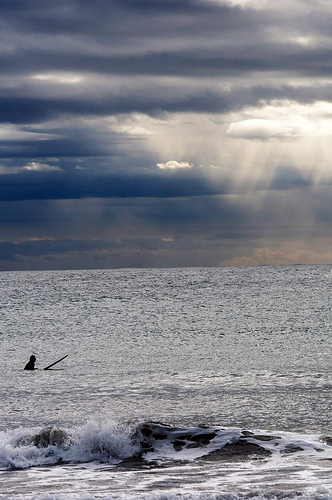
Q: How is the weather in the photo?
A: It is cloudy.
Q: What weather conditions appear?
A: It is cloudy.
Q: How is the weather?
A: It is cloudy.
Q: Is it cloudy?
A: Yes, it is cloudy.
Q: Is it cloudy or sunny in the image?
A: It is cloudy.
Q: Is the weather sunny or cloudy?
A: It is cloudy.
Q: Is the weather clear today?
A: No, it is cloudy.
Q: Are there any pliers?
A: No, there are no pliers.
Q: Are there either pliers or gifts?
A: No, there are no pliers or gifts.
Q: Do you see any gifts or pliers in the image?
A: No, there are no pliers or gifts.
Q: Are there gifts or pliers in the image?
A: No, there are no pliers or gifts.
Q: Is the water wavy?
A: Yes, the water is wavy.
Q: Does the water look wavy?
A: Yes, the water is wavy.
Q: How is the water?
A: The water is wavy.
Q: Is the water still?
A: No, the water is wavy.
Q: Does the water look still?
A: No, the water is wavy.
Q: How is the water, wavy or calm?
A: The water is wavy.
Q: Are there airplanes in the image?
A: No, there are no airplanes.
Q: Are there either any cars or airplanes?
A: No, there are no airplanes or cars.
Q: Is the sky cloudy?
A: Yes, the sky is cloudy.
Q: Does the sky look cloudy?
A: Yes, the sky is cloudy.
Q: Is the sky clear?
A: No, the sky is cloudy.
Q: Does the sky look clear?
A: No, the sky is cloudy.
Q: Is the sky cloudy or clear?
A: The sky is cloudy.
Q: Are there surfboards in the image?
A: Yes, there is a surfboard.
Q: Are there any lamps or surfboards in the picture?
A: Yes, there is a surfboard.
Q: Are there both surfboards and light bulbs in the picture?
A: No, there is a surfboard but no light bulbs.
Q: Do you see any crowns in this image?
A: No, there are no crowns.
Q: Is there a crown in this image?
A: No, there are no crowns.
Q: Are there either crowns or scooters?
A: No, there are no crowns or scooters.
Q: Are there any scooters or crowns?
A: No, there are no crowns or scooters.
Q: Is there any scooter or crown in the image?
A: No, there are no crowns or scooters.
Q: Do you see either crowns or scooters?
A: No, there are no crowns or scooters.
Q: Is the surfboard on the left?
A: Yes, the surfboard is on the left of the image.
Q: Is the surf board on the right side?
A: No, the surf board is on the left of the image.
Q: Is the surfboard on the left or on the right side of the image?
A: The surfboard is on the left of the image.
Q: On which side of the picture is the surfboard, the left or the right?
A: The surfboard is on the left of the image.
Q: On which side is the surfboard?
A: The surfboard is on the left of the image.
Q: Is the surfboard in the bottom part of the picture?
A: Yes, the surfboard is in the bottom of the image.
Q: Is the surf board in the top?
A: No, the surf board is in the bottom of the image.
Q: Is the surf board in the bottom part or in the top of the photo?
A: The surf board is in the bottom of the image.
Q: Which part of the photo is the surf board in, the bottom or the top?
A: The surf board is in the bottom of the image.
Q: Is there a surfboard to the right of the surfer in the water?
A: Yes, there is a surfboard to the right of the surfer.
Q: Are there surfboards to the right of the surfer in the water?
A: Yes, there is a surfboard to the right of the surfer.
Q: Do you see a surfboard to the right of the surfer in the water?
A: Yes, there is a surfboard to the right of the surfer.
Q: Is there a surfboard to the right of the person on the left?
A: Yes, there is a surfboard to the right of the surfer.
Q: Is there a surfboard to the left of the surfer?
A: No, the surfboard is to the right of the surfer.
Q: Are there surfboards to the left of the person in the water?
A: No, the surfboard is to the right of the surfer.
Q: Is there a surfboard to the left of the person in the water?
A: No, the surfboard is to the right of the surfer.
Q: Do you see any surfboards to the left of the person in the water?
A: No, the surfboard is to the right of the surfer.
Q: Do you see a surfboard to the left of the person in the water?
A: No, the surfboard is to the right of the surfer.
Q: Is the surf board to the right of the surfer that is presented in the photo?
A: Yes, the surf board is to the right of the surfer.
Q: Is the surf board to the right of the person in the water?
A: Yes, the surf board is to the right of the surfer.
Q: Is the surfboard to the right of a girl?
A: No, the surfboard is to the right of the surfer.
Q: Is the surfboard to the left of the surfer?
A: No, the surfboard is to the right of the surfer.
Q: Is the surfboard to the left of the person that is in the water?
A: No, the surfboard is to the right of the surfer.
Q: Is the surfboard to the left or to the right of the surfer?
A: The surfboard is to the right of the surfer.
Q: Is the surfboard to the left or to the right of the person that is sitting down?
A: The surfboard is to the right of the surfer.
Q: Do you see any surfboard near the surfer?
A: Yes, there is a surfboard near the surfer.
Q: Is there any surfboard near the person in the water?
A: Yes, there is a surfboard near the surfer.